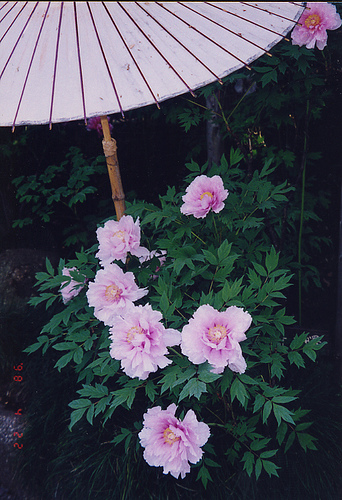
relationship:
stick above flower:
[87, 121, 147, 231] [137, 400, 212, 481]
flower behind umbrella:
[175, 298, 258, 386] [1, 0, 308, 139]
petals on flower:
[177, 412, 212, 444] [117, 395, 204, 479]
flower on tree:
[143, 403, 208, 482] [67, 152, 319, 493]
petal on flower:
[173, 170, 233, 217] [124, 408, 217, 477]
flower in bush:
[137, 400, 212, 481] [49, 253, 317, 472]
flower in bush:
[179, 301, 252, 375] [49, 253, 317, 472]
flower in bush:
[107, 298, 181, 378] [49, 253, 317, 472]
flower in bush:
[90, 214, 152, 265] [49, 253, 317, 472]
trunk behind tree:
[199, 93, 227, 168] [21, 134, 330, 500]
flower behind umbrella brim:
[287, 0, 340, 51] [0, 2, 312, 138]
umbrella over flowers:
[0, 4, 313, 126] [60, 175, 251, 480]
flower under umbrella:
[180, 165, 239, 216] [2, 1, 303, 222]